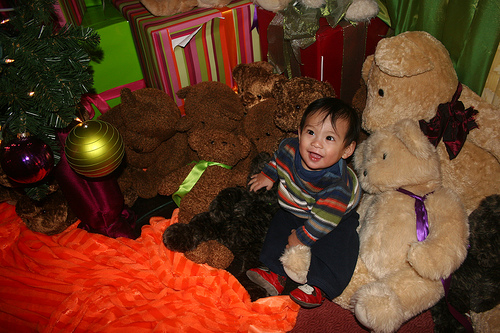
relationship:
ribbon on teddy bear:
[173, 160, 228, 206] [160, 125, 248, 259]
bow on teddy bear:
[417, 78, 479, 168] [359, 28, 499, 215]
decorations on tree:
[10, 12, 112, 192] [1, 0, 118, 214]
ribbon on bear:
[172, 160, 234, 208] [328, 123, 498, 310]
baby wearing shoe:
[243, 97, 368, 310] [289, 280, 323, 310]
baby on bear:
[243, 97, 368, 310] [157, 128, 258, 268]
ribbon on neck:
[392, 185, 444, 244] [366, 183, 438, 194]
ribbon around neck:
[172, 160, 234, 208] [184, 156, 236, 168]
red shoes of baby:
[247, 264, 322, 309] [243, 97, 368, 310]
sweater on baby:
[261, 138, 354, 246] [248, 90, 366, 306]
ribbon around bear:
[392, 185, 444, 244] [338, 140, 460, 325]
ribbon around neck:
[172, 160, 234, 208] [195, 152, 230, 169]